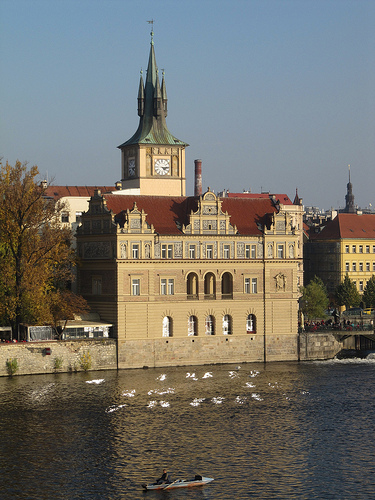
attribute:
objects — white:
[76, 371, 310, 443]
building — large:
[79, 184, 309, 337]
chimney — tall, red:
[191, 154, 204, 198]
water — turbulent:
[289, 357, 361, 421]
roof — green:
[117, 27, 192, 147]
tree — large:
[0, 154, 72, 344]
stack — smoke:
[191, 155, 204, 196]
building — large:
[82, 15, 305, 368]